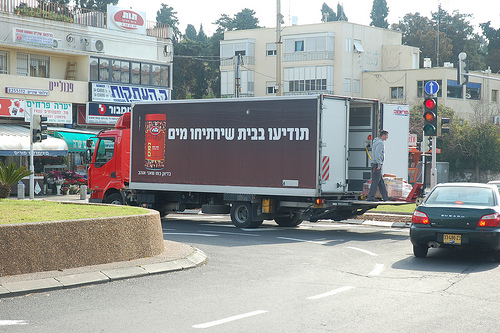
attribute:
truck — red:
[85, 106, 133, 201]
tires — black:
[218, 186, 283, 243]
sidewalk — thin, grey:
[1, 234, 210, 306]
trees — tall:
[414, 15, 477, 60]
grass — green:
[8, 189, 138, 222]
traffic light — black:
[417, 92, 438, 140]